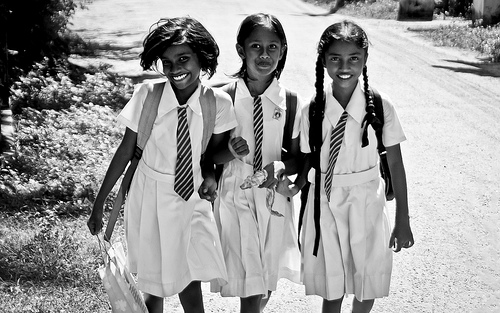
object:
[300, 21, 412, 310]
person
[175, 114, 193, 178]
stripe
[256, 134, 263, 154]
stripe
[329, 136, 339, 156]
stripe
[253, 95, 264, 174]
tie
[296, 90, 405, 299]
school uniform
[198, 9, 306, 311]
person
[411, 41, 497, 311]
street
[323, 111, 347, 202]
tie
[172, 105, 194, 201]
tie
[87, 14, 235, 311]
person